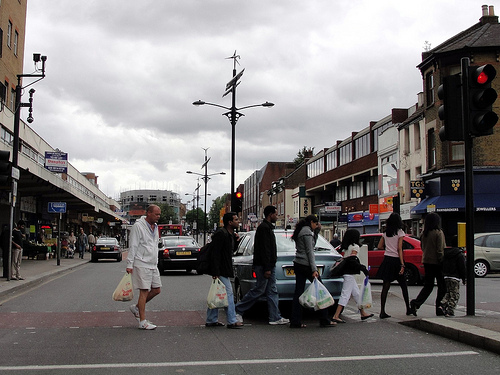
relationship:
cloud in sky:
[275, 20, 368, 134] [18, 0, 499, 207]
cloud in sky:
[68, 2, 301, 45] [25, 1, 498, 185]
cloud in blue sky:
[275, 20, 368, 134] [283, 35, 369, 92]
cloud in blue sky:
[275, 20, 368, 134] [18, 0, 499, 207]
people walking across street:
[408, 212, 445, 320] [2, 200, 498, 373]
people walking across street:
[380, 216, 418, 318] [2, 200, 498, 373]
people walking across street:
[324, 226, 378, 328] [2, 200, 498, 373]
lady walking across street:
[287, 214, 338, 330] [2, 200, 498, 373]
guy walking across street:
[192, 204, 250, 319] [2, 200, 498, 373]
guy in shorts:
[116, 194, 174, 329] [126, 260, 175, 302]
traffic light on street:
[429, 58, 496, 148] [7, 250, 497, 373]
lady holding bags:
[298, 214, 317, 282] [295, 277, 332, 312]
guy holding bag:
[116, 194, 174, 329] [109, 271, 139, 304]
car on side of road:
[87, 232, 126, 265] [0, 259, 494, 370]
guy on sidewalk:
[116, 194, 174, 329] [409, 313, 496, 363]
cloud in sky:
[34, 20, 369, 152] [78, 30, 159, 131]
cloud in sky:
[275, 20, 368, 134] [78, 30, 159, 131]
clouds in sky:
[148, 107, 190, 147] [123, 42, 184, 81]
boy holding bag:
[209, 214, 242, 324] [197, 232, 228, 274]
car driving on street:
[233, 221, 358, 326] [33, 282, 103, 348]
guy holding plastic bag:
[192, 204, 250, 319] [198, 275, 236, 309]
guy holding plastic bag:
[252, 210, 297, 322] [282, 267, 334, 308]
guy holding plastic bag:
[116, 194, 174, 329] [356, 275, 383, 311]